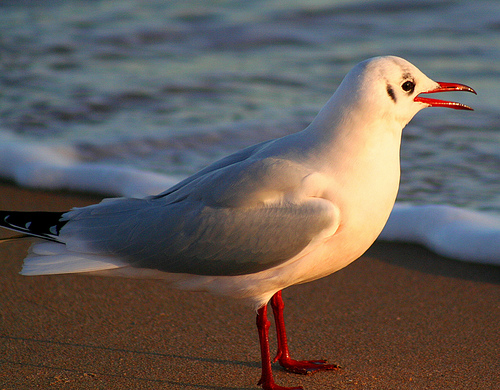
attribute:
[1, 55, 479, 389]
gull — red billed, standing, black, walking, calling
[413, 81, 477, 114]
beak — red, orange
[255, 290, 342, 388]
legs — red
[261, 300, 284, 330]
knees — knobby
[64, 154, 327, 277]
wings — grey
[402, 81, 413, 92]
eye — dark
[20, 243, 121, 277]
tail — white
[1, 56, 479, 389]
bird — standing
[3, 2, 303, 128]
water — small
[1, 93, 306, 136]
waves — small